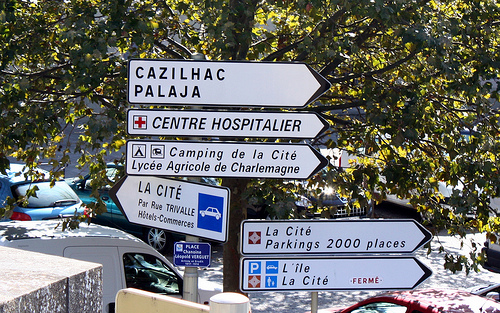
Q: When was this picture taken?
A: Daytime.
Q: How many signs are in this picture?
A: Seven.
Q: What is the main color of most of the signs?
A: White.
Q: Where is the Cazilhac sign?
A: On top.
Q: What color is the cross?
A: Red.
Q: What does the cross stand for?
A: Hospital.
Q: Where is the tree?
A: Behind the signs.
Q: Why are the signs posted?
A: Direction.